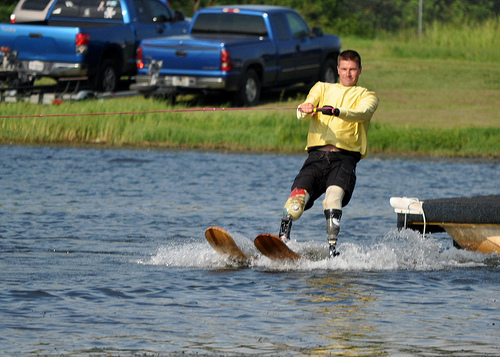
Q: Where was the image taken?
A: It was taken at the field.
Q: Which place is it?
A: It is a field.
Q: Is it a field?
A: Yes, it is a field.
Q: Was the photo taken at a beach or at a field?
A: It was taken at a field.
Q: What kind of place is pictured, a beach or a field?
A: It is a field.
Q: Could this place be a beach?
A: No, it is a field.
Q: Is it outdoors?
A: Yes, it is outdoors.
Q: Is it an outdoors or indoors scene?
A: It is outdoors.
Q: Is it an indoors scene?
A: No, it is outdoors.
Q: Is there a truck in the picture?
A: Yes, there is a truck.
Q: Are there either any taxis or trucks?
A: Yes, there is a truck.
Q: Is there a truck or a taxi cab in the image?
A: Yes, there is a truck.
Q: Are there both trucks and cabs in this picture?
A: No, there is a truck but no taxis.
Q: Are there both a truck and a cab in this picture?
A: No, there is a truck but no taxis.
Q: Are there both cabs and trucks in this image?
A: No, there is a truck but no taxis.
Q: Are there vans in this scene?
A: No, there are no vans.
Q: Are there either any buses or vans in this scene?
A: No, there are no vans or buses.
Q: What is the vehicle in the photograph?
A: The vehicle is a truck.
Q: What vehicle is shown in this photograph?
A: The vehicle is a truck.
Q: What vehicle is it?
A: The vehicle is a truck.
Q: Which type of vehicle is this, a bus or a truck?
A: This is a truck.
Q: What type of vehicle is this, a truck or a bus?
A: This is a truck.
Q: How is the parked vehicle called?
A: The vehicle is a truck.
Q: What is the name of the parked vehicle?
A: The vehicle is a truck.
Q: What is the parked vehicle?
A: The vehicle is a truck.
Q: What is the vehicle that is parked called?
A: The vehicle is a truck.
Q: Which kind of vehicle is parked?
A: The vehicle is a truck.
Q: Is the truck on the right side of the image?
A: No, the truck is on the left of the image.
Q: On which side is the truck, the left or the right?
A: The truck is on the left of the image.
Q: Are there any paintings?
A: No, there are no paintings.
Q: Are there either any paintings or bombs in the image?
A: No, there are no paintings or bombs.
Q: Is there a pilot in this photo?
A: No, there are no pilots.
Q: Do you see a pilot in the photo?
A: No, there are no pilots.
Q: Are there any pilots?
A: No, there are no pilots.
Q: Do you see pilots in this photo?
A: No, there are no pilots.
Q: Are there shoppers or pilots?
A: No, there are no pilots or shoppers.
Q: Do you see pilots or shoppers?
A: No, there are no pilots or shoppers.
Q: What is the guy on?
A: The guy is on the ski.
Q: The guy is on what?
A: The guy is on the ski.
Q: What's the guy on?
A: The guy is on the ski.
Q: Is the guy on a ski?
A: Yes, the guy is on a ski.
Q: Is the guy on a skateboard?
A: No, the guy is on a ski.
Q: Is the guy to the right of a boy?
A: No, the guy is to the right of a ski.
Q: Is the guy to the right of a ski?
A: Yes, the guy is to the right of a ski.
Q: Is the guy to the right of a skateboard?
A: No, the guy is to the right of a ski.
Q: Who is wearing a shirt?
A: The guy is wearing a shirt.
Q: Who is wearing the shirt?
A: The guy is wearing a shirt.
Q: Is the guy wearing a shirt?
A: Yes, the guy is wearing a shirt.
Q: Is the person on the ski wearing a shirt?
A: Yes, the guy is wearing a shirt.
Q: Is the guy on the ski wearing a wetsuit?
A: No, the guy is wearing a shirt.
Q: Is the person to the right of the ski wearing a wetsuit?
A: No, the guy is wearing a shirt.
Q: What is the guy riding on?
A: The guy is riding on the ski.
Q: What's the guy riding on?
A: The guy is riding on the ski.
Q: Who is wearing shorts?
A: The guy is wearing shorts.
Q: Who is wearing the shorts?
A: The guy is wearing shorts.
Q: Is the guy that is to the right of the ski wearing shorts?
A: Yes, the guy is wearing shorts.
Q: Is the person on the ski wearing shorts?
A: Yes, the guy is wearing shorts.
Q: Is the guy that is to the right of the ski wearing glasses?
A: No, the guy is wearing shorts.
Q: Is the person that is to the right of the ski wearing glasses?
A: No, the guy is wearing shorts.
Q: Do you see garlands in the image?
A: No, there are no garlands.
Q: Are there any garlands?
A: No, there are no garlands.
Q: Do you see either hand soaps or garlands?
A: No, there are no garlands or hand soaps.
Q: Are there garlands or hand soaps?
A: No, there are no garlands or hand soaps.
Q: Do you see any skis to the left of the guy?
A: Yes, there is a ski to the left of the guy.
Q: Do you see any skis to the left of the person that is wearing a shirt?
A: Yes, there is a ski to the left of the guy.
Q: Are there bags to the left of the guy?
A: No, there is a ski to the left of the guy.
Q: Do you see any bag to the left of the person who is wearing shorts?
A: No, there is a ski to the left of the guy.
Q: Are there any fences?
A: No, there are no fences.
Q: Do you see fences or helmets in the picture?
A: No, there are no fences or helmets.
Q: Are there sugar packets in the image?
A: No, there are no sugar packets.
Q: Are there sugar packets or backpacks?
A: No, there are no sugar packets or backpacks.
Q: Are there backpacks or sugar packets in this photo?
A: No, there are no sugar packets or backpacks.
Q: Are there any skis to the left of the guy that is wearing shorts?
A: Yes, there is a ski to the left of the guy.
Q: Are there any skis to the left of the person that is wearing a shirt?
A: Yes, there is a ski to the left of the guy.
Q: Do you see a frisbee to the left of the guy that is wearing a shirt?
A: No, there is a ski to the left of the guy.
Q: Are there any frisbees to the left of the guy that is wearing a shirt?
A: No, there is a ski to the left of the guy.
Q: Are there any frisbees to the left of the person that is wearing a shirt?
A: No, there is a ski to the left of the guy.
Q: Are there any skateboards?
A: No, there are no skateboards.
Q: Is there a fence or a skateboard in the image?
A: No, there are no skateboards or fences.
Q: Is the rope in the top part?
A: Yes, the rope is in the top of the image.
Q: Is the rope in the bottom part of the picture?
A: No, the rope is in the top of the image.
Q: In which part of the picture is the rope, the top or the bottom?
A: The rope is in the top of the image.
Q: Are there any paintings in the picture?
A: No, there are no paintings.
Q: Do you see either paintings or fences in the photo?
A: No, there are no paintings or fences.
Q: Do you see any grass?
A: Yes, there is grass.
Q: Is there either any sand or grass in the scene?
A: Yes, there is grass.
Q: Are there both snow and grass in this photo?
A: No, there is grass but no snow.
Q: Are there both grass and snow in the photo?
A: No, there is grass but no snow.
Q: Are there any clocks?
A: No, there are no clocks.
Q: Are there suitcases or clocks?
A: No, there are no clocks or suitcases.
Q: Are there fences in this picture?
A: No, there are no fences.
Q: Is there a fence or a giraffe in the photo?
A: No, there are no fences or giraffes.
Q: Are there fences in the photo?
A: No, there are no fences.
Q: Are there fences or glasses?
A: No, there are no fences or glasses.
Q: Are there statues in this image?
A: No, there are no statues.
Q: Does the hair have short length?
A: Yes, the hair is short.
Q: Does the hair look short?
A: Yes, the hair is short.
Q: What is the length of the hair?
A: The hair is short.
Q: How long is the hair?
A: The hair is short.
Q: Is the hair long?
A: No, the hair is short.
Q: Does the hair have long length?
A: No, the hair is short.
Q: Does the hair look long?
A: No, the hair is short.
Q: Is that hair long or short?
A: The hair is short.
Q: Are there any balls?
A: No, there are no balls.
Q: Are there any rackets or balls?
A: No, there are no balls or rackets.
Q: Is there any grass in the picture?
A: Yes, there is grass.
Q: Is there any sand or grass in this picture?
A: Yes, there is grass.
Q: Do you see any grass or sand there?
A: Yes, there is grass.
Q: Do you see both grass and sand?
A: No, there is grass but no sand.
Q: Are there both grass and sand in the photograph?
A: No, there is grass but no sand.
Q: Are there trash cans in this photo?
A: No, there are no trash cans.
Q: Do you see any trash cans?
A: No, there are no trash cans.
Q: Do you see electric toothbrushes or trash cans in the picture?
A: No, there are no trash cans or electric toothbrushes.